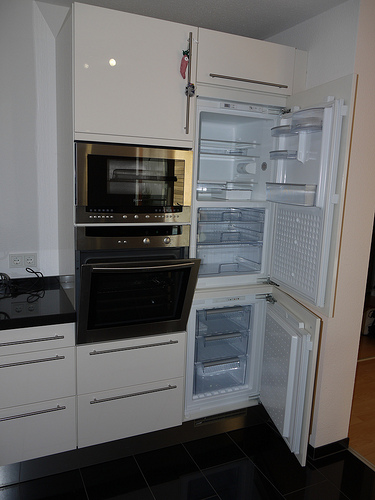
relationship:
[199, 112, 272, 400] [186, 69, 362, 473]
inside of a refrigerator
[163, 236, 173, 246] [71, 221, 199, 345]
knob on oven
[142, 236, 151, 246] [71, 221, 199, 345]
knob on oven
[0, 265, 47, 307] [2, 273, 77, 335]
cord on top of counter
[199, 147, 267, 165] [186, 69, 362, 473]
shelf inside refrigerator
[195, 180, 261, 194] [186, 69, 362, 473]
shelf inside refrigerator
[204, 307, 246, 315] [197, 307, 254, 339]
handle on a drawer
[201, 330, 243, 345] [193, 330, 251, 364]
handle on a drawer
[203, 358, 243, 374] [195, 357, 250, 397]
handle on a drawer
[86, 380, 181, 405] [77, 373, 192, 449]
handle on a drawer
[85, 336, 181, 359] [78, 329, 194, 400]
handle on a drawer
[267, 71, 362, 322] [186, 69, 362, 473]
door of a refrigerator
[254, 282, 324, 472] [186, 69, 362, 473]
door of a refrigerator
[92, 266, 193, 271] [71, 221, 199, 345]
handle on oven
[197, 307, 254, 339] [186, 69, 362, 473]
drawer in refrigerator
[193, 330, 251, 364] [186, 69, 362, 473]
drawer in refrigerator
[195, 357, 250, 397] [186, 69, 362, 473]
drawer in refrigerator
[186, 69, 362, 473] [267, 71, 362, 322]
refrigerator has door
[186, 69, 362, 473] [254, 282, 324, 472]
refrigerator has door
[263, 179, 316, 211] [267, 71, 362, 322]
tray in door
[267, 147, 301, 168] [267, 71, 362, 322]
tray in door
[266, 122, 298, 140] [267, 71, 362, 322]
tray in door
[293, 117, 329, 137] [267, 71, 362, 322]
tray in door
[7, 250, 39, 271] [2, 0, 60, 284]
socket in wall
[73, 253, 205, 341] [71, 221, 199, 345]
door of oven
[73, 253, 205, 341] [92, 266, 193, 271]
door has handle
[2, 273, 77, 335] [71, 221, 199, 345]
counter next to oven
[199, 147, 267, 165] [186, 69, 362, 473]
shelf inside of refrigerator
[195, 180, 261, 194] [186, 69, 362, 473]
shelf inside of refrigerator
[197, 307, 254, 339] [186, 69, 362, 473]
drawer inside of refrigerator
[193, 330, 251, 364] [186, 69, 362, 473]
drawer inside of refrigerator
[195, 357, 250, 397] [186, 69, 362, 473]
drawer inside of refrigerator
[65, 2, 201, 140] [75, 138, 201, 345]
cabinet above oven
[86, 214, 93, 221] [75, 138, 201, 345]
button on oven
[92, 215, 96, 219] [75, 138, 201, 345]
button on oven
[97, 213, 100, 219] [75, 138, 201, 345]
button on oven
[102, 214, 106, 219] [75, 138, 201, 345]
button on oven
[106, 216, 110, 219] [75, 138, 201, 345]
button on oven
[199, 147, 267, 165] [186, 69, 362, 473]
shelf inside of a refrigerator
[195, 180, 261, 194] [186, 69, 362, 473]
shelf inside of a refrigerator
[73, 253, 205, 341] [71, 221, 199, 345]
door of an oven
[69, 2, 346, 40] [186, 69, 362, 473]
ceiling above refrigerator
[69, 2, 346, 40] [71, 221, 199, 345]
ceiling above oven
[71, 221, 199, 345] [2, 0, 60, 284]
oven built into wall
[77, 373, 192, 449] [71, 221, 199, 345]
drawer under oven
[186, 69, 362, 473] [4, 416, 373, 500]
refrigerator on top of floor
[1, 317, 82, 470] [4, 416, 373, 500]
cabinet on top of floor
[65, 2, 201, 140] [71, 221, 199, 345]
cabinet over oven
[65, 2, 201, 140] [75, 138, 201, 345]
cabinet over oven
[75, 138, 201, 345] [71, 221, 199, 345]
oven above oven